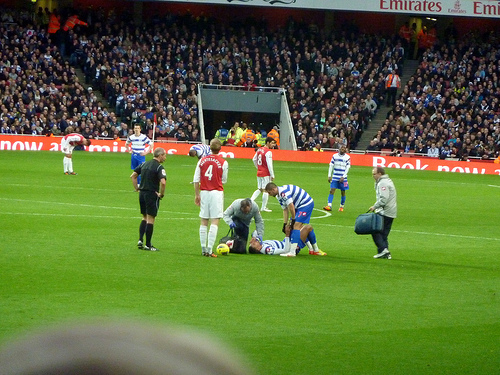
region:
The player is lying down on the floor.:
[239, 219, 354, 270]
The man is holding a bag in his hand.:
[346, 165, 417, 270]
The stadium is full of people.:
[4, 20, 497, 136]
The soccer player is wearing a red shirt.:
[184, 136, 243, 261]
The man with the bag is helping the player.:
[212, 180, 335, 262]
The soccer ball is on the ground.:
[206, 225, 237, 270]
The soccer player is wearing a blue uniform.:
[319, 137, 356, 216]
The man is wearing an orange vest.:
[374, 58, 404, 114]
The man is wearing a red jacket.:
[232, 76, 267, 96]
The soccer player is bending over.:
[49, 128, 100, 183]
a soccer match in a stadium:
[19, 24, 476, 364]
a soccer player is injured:
[205, 191, 335, 283]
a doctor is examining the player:
[228, 190, 269, 253]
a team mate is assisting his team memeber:
[242, 177, 324, 274]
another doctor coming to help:
[347, 158, 413, 263]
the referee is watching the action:
[123, 144, 180, 264]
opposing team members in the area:
[196, 124, 280, 182]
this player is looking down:
[47, 128, 104, 198]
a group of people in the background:
[206, 112, 277, 144]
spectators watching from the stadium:
[23, 27, 445, 142]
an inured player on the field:
[33, 24, 466, 359]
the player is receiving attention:
[234, 160, 406, 290]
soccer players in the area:
[42, 113, 428, 268]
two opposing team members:
[192, 114, 272, 246]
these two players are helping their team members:
[268, 139, 368, 206]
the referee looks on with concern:
[117, 139, 184, 256]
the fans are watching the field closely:
[27, 22, 474, 148]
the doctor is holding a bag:
[355, 164, 406, 266]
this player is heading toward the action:
[114, 121, 160, 181]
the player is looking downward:
[51, 124, 101, 168]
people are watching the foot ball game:
[6, 8, 496, 300]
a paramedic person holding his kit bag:
[351, 163, 408, 278]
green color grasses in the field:
[8, 255, 495, 367]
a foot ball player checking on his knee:
[59, 131, 90, 175]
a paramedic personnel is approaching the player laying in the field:
[248, 165, 408, 266]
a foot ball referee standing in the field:
[128, 145, 166, 252]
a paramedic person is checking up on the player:
[217, 199, 329, 259]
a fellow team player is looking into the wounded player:
[249, 180, 326, 260]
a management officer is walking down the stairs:
[374, 64, 401, 119]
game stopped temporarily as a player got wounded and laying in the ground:
[47, 123, 418, 270]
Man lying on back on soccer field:
[248, 226, 326, 256]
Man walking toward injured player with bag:
[352, 163, 399, 265]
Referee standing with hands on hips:
[129, 146, 168, 251]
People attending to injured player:
[223, 178, 325, 257]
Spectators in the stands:
[0, 14, 498, 156]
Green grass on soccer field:
[1, 150, 498, 371]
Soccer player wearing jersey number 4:
[190, 140, 228, 257]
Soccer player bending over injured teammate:
[265, 180, 317, 262]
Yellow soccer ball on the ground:
[214, 241, 229, 256]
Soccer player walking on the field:
[323, 143, 351, 214]